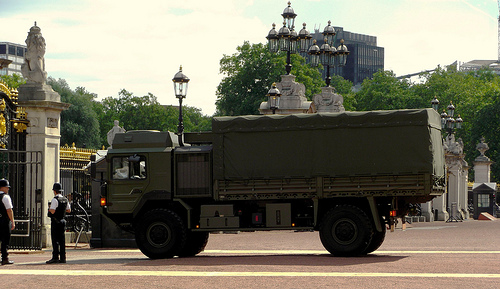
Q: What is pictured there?
A: Truck.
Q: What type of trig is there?
A: Military.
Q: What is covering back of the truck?
A: Green canvas.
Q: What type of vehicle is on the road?
A: Military.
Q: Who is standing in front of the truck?
A: Two officers.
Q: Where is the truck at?
A: On road in front of gate.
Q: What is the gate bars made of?
A: Metal bars.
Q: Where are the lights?
A: On lamp posts.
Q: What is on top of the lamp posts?
A: Lanterns.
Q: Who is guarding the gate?
A: Police.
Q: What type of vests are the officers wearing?
A: Black bulletproof.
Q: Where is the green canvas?
A: On back of truck.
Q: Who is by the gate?
A: Police guards.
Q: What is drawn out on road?
A: Lines.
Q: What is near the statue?
A: Truck.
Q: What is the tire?
A: Back left.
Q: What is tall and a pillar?
A: Fence.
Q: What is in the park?
A: Pillars.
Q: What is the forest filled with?
A: Trees.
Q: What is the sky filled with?
A: Clouds.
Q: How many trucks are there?
A: 1.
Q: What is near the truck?
A: A police.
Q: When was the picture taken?
A: During the day.